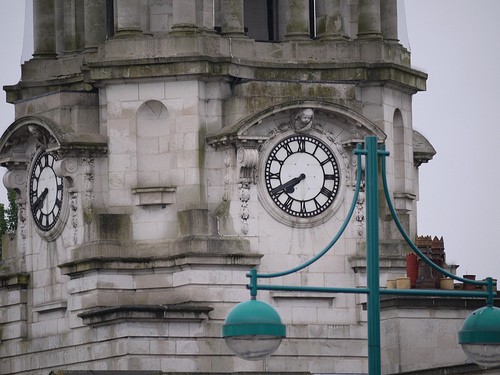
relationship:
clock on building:
[265, 135, 339, 218] [1, 0, 498, 374]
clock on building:
[29, 151, 64, 230] [1, 0, 498, 374]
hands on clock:
[271, 173, 304, 196] [265, 135, 339, 218]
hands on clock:
[30, 188, 48, 210] [29, 151, 64, 230]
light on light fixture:
[224, 298, 285, 363] [221, 134, 499, 374]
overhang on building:
[411, 129, 435, 164] [1, 0, 498, 374]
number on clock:
[296, 139, 306, 153] [265, 135, 339, 218]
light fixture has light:
[221, 134, 499, 374] [224, 298, 285, 363]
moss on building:
[287, 15, 311, 37] [1, 0, 498, 374]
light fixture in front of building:
[221, 134, 499, 374] [1, 0, 498, 374]